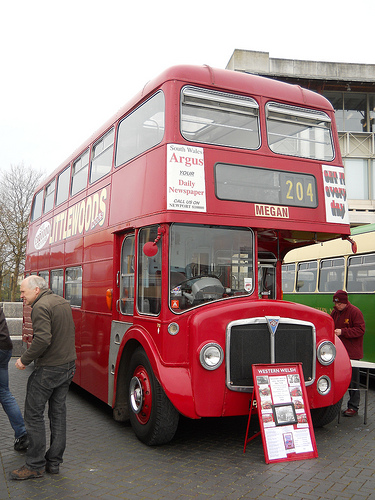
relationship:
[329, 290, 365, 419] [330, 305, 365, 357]
man wearing coat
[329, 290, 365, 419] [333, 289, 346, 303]
man wearing cap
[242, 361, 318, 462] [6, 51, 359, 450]
sign in front of bus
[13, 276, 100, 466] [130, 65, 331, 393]
man next to bus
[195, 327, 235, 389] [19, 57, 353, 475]
headlight on bus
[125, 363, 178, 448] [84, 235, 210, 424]
wheel on bus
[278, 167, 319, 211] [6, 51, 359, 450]
number on bus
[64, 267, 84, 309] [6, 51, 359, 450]
window on bus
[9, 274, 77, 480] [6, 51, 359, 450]
man near bus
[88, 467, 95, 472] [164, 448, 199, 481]
debris on ground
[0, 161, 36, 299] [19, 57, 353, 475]
tree behind bus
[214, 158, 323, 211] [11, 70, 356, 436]
display on bus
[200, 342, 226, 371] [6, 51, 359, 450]
headlight bus bus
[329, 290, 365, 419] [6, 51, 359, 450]
man standing near bus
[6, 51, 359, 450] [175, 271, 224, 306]
bus has wheel